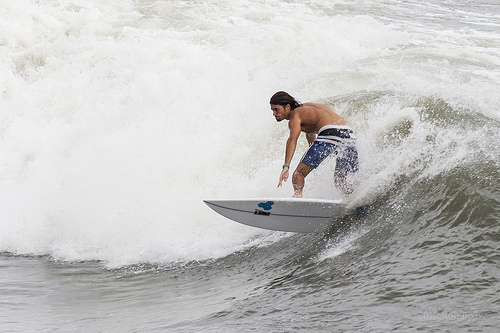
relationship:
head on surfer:
[269, 92, 301, 122] [271, 90, 360, 199]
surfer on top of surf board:
[271, 90, 360, 199] [202, 198, 357, 235]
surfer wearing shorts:
[271, 90, 360, 199] [301, 122, 360, 173]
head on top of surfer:
[269, 92, 301, 122] [271, 90, 360, 199]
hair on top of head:
[272, 92, 303, 110] [269, 92, 301, 122]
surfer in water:
[271, 90, 360, 199] [7, 7, 496, 329]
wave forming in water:
[287, 92, 500, 269] [7, 7, 496, 329]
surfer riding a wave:
[271, 90, 360, 199] [287, 92, 500, 269]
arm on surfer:
[279, 117, 303, 168] [271, 90, 360, 199]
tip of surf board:
[203, 196, 342, 235] [202, 198, 357, 235]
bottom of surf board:
[206, 199, 345, 234] [202, 198, 357, 235]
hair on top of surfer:
[272, 92, 303, 110] [271, 90, 360, 199]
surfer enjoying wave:
[271, 90, 360, 199] [287, 92, 500, 269]